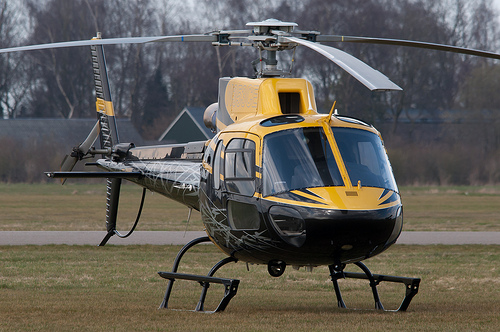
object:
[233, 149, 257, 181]
window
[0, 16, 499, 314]
helicopter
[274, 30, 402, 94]
rotor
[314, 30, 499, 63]
rotor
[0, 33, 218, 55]
rotor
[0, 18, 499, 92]
wings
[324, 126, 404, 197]
window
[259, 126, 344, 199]
window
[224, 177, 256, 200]
window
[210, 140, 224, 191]
window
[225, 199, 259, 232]
window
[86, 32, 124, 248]
tail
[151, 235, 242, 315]
leg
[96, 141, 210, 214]
back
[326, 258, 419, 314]
leg